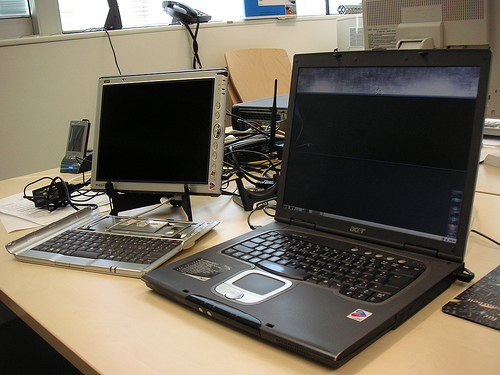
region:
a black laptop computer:
[141, 47, 493, 369]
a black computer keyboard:
[34, 228, 182, 267]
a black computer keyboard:
[224, 232, 424, 304]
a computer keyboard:
[234, 271, 286, 296]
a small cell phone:
[66, 118, 89, 159]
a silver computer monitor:
[89, 68, 227, 193]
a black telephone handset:
[159, 0, 211, 71]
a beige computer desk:
[0, 130, 498, 373]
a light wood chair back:
[224, 47, 292, 102]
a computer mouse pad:
[441, 262, 498, 334]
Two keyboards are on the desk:
[34, 181, 453, 373]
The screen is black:
[276, 64, 494, 250]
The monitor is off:
[83, 50, 397, 325]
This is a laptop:
[285, 50, 470, 373]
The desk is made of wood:
[44, 276, 173, 372]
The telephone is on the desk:
[162, 10, 227, 40]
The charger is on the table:
[47, 135, 99, 182]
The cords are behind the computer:
[222, 116, 324, 234]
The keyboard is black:
[240, 214, 362, 311]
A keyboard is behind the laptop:
[350, 10, 490, 92]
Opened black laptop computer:
[140, 45, 495, 370]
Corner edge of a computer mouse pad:
[439, 261, 499, 336]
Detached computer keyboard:
[4, 206, 223, 279]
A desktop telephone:
[158, 0, 213, 68]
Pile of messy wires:
[220, 102, 287, 224]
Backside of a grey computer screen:
[360, 1, 498, 121]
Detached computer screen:
[90, 66, 230, 198]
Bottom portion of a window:
[54, 0, 368, 33]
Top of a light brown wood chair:
[218, 46, 295, 103]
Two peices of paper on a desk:
[1, 187, 111, 233]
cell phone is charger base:
[57, 113, 95, 175]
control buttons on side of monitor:
[210, 67, 227, 197]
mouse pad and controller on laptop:
[218, 266, 285, 306]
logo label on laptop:
[342, 305, 370, 323]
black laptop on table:
[140, 43, 494, 363]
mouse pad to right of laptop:
[439, 252, 499, 337]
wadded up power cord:
[24, 173, 99, 213]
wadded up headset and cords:
[220, 140, 280, 229]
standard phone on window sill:
[157, 0, 212, 70]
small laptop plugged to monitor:
[5, 205, 220, 281]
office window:
[55, 0, 364, 34]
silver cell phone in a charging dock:
[59, 120, 94, 174]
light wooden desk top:
[0, 123, 499, 373]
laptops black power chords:
[22, 154, 105, 211]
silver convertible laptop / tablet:
[4, 66, 229, 278]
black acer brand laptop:
[141, 47, 491, 368]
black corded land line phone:
[162, 0, 211, 70]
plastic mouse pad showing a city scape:
[440, 263, 499, 331]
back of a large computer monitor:
[361, 0, 494, 51]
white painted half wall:
[0, 15, 361, 179]